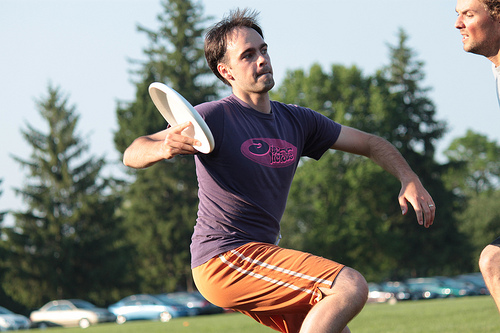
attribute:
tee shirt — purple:
[166, 92, 342, 269]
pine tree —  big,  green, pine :
[0, 83, 135, 309]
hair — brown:
[203, 7, 263, 85]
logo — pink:
[224, 122, 312, 187]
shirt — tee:
[207, 107, 291, 249]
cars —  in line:
[326, 252, 458, 312]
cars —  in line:
[12, 253, 185, 323]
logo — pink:
[239, 136, 299, 169]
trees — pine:
[0, 0, 497, 315]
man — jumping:
[116, 7, 441, 331]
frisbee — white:
[131, 77, 218, 164]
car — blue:
[62, 286, 327, 331]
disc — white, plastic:
[148, 78, 216, 155]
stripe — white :
[230, 249, 332, 289]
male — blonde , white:
[127, 8, 439, 328]